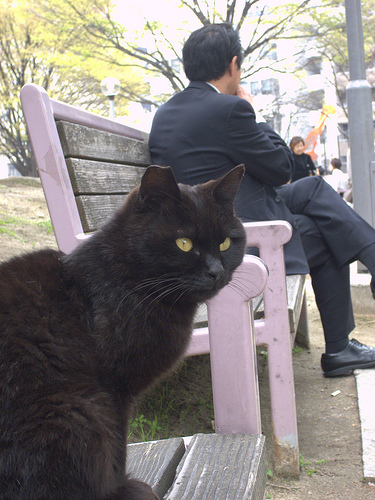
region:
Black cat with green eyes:
[0, 151, 274, 414]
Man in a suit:
[128, 15, 374, 383]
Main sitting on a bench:
[4, 21, 374, 390]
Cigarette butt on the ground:
[311, 380, 355, 405]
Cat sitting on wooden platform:
[1, 144, 284, 497]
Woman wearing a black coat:
[280, 123, 322, 189]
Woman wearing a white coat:
[319, 146, 358, 203]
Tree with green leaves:
[0, 0, 144, 180]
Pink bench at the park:
[13, 76, 359, 475]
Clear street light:
[86, 69, 136, 128]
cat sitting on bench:
[1, 165, 251, 499]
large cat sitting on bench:
[0, 164, 244, 497]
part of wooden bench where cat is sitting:
[127, 431, 272, 499]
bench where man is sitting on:
[23, 82, 366, 475]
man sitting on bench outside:
[153, 23, 373, 378]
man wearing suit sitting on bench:
[148, 24, 374, 377]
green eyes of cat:
[175, 234, 232, 254]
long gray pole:
[345, 0, 372, 275]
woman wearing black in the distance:
[288, 135, 316, 178]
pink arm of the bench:
[204, 259, 267, 433]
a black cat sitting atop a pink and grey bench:
[1, 164, 269, 499]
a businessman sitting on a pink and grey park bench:
[19, 24, 374, 480]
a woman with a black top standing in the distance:
[289, 136, 316, 183]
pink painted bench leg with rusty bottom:
[265, 341, 298, 477]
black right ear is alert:
[140, 164, 179, 207]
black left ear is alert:
[198, 163, 244, 215]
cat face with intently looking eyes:
[173, 231, 237, 301]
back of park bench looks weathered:
[56, 119, 150, 230]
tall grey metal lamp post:
[343, 1, 373, 272]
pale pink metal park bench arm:
[206, 254, 267, 432]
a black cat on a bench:
[1, 165, 256, 499]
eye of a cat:
[173, 235, 192, 252]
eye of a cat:
[216, 232, 231, 252]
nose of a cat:
[200, 254, 225, 280]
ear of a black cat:
[212, 160, 245, 208]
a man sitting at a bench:
[150, 20, 373, 375]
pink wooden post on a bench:
[251, 220, 299, 478]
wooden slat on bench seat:
[166, 430, 268, 497]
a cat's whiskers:
[116, 269, 267, 324]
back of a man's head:
[183, 23, 243, 97]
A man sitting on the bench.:
[178, 34, 301, 249]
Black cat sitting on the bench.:
[6, 159, 219, 397]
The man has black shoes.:
[326, 336, 369, 378]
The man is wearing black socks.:
[327, 337, 347, 353]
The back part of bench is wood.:
[49, 110, 122, 209]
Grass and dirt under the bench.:
[166, 381, 199, 418]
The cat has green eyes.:
[165, 229, 243, 256]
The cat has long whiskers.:
[134, 267, 202, 308]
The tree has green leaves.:
[64, 16, 152, 99]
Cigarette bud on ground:
[329, 378, 350, 405]